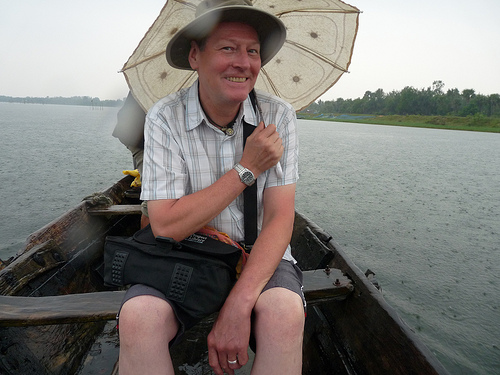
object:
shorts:
[117, 247, 304, 350]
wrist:
[216, 295, 253, 322]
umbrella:
[116, 0, 362, 180]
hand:
[206, 316, 250, 373]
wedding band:
[226, 358, 235, 367]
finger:
[228, 349, 241, 369]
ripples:
[433, 192, 446, 204]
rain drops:
[399, 288, 416, 304]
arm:
[218, 103, 298, 318]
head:
[185, 1, 262, 106]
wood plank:
[0, 269, 352, 326]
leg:
[114, 278, 184, 374]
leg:
[250, 259, 306, 374]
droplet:
[99, 79, 141, 143]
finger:
[247, 105, 304, 190]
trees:
[296, 82, 499, 117]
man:
[115, 0, 305, 373]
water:
[78, 315, 347, 374]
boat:
[0, 154, 451, 374]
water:
[0, 99, 498, 372]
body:
[115, 80, 304, 375]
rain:
[297, 0, 497, 356]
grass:
[300, 109, 498, 135]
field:
[294, 111, 496, 132]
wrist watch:
[233, 162, 255, 188]